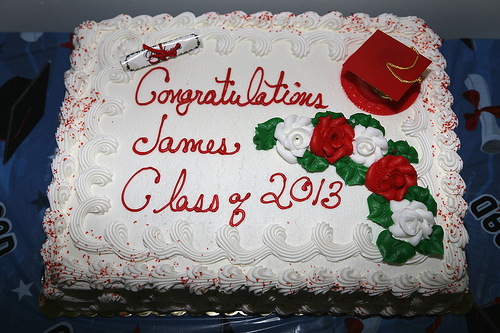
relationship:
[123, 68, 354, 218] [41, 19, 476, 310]
writing on cake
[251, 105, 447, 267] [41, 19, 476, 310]
flowers on cake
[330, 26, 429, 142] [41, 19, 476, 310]
hat on cake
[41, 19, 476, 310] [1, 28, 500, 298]
cake on cloth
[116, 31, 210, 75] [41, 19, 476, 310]
diploma on cake